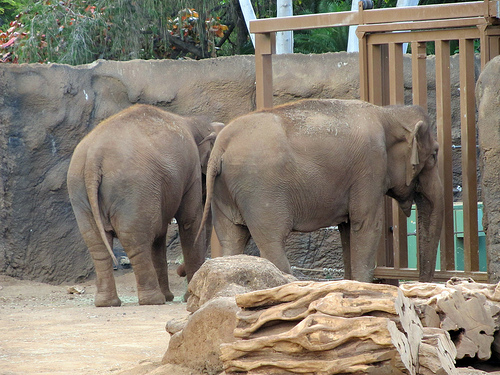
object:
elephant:
[64, 103, 222, 306]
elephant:
[185, 97, 445, 285]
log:
[111, 253, 500, 375]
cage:
[0, 0, 500, 375]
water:
[457, 204, 483, 224]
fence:
[246, 0, 500, 285]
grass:
[0, 0, 350, 63]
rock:
[113, 253, 500, 375]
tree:
[147, 0, 243, 63]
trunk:
[170, 22, 236, 59]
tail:
[191, 140, 224, 249]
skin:
[309, 103, 369, 168]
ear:
[406, 120, 427, 187]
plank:
[269, 294, 353, 343]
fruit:
[208, 17, 229, 38]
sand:
[0, 278, 186, 375]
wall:
[0, 50, 500, 287]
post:
[457, 39, 479, 270]